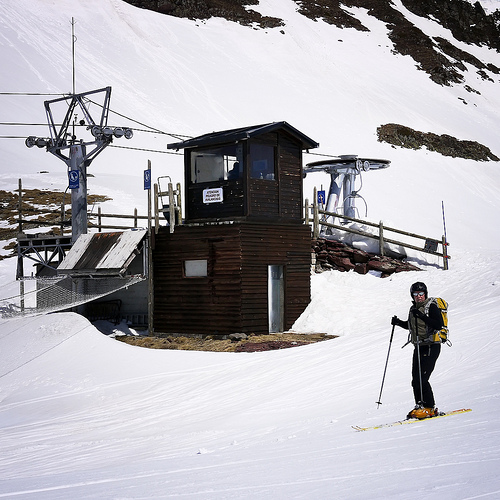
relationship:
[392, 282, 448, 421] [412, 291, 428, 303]
skier has face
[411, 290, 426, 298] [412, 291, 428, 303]
goggles on face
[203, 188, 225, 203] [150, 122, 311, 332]
sign on building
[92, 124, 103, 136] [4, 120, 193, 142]
roller supporting cable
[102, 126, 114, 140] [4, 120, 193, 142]
roller supporting cable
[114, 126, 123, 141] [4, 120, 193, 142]
roller supporting cable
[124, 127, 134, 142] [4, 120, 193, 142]
roller supporting cable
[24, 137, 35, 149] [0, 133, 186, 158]
roller supporting cable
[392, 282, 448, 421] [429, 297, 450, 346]
man carrying backpack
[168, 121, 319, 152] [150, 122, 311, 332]
roof on building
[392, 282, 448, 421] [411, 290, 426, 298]
man wearing goggles